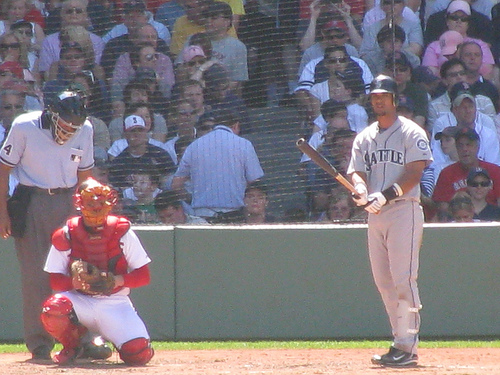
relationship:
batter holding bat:
[348, 75, 435, 367] [294, 137, 356, 195]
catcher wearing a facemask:
[40, 178, 156, 366] [77, 183, 116, 229]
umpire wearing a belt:
[2, 92, 96, 359] [31, 188, 65, 195]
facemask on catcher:
[77, 183, 116, 229] [40, 178, 156, 366]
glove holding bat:
[365, 186, 401, 210] [294, 137, 356, 195]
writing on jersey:
[366, 149, 404, 174] [347, 117, 433, 204]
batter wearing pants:
[348, 75, 435, 367] [366, 200, 426, 355]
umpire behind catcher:
[2, 92, 96, 359] [40, 178, 156, 366]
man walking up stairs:
[172, 109, 265, 223] [248, 99, 306, 218]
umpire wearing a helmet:
[2, 92, 96, 359] [54, 91, 86, 128]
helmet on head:
[369, 75, 400, 107] [371, 92, 396, 119]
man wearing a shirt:
[433, 132, 499, 203] [431, 158, 498, 203]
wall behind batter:
[0, 223, 500, 337] [348, 75, 435, 367]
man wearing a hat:
[114, 116, 176, 185] [121, 115, 147, 132]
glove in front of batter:
[365, 186, 401, 210] [348, 75, 435, 367]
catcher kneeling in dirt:
[40, 178, 156, 366] [2, 349, 500, 374]